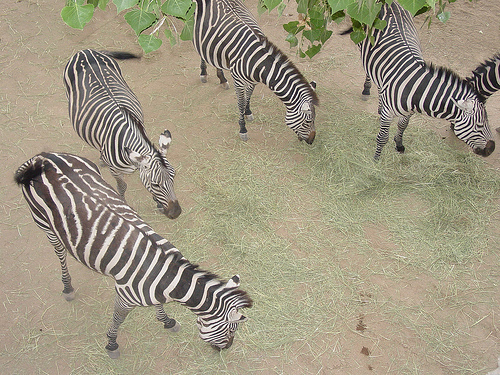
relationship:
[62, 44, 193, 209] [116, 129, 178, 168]
zebra has ears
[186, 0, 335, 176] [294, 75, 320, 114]
zebra has ears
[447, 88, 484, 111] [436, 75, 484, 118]
zebra has ears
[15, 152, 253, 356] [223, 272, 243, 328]
zebra has ears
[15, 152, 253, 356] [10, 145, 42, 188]
zebra has tail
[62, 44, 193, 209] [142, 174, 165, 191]
zebra has eye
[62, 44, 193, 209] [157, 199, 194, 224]
zebra has nose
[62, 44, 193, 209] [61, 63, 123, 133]
zebra has stripes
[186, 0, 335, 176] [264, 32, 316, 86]
zebra has main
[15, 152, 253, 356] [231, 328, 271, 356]
zebra q eating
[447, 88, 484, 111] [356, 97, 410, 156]
zebra has legs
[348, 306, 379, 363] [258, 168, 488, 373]
spots on ground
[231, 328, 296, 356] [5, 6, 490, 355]
eating beneath zebras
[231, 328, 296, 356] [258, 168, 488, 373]
eating on ground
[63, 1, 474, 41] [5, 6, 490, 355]
branches over zebras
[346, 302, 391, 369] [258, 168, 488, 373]
water on ground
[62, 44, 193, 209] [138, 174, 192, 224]
zebra has face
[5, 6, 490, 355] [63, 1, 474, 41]
zebras under branches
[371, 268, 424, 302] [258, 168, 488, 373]
dirt on ground